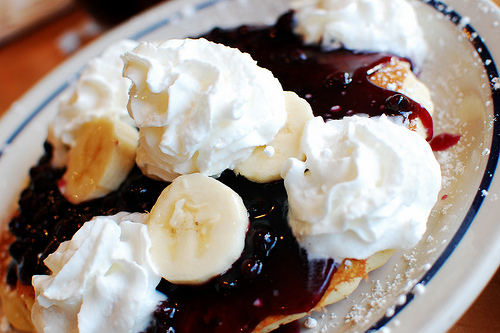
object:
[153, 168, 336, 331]
jelly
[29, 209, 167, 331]
cream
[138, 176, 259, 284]
banana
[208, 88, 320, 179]
banana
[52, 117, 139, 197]
banana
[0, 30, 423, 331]
pancake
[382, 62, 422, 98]
powdered sugar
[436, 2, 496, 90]
rim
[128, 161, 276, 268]
slice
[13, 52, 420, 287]
breakfast food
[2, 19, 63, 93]
table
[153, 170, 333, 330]
blueberry glaze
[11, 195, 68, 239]
blueberry glaze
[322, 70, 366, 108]
blueberry glaze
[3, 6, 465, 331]
blueberry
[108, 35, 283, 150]
whipped cream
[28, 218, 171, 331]
whipped cream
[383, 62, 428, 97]
pancake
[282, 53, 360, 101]
syrup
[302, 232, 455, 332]
sugar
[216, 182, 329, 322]
blueberry sauce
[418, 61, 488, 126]
sugar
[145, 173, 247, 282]
banana slice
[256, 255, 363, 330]
side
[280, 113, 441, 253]
cream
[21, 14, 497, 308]
plate